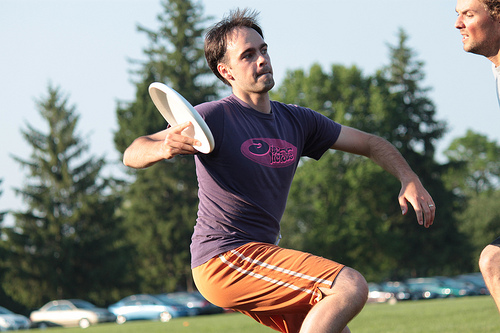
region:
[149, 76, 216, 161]
the frisbee is white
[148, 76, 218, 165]
man holding the frisbee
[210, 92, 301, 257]
the shirt is purple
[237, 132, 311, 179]
the logo is pink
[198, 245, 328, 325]
the shorts are orange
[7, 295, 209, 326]
the cars are parked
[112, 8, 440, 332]
jumping man holding frisbee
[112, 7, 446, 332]
white adult brown haired male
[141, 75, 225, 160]
white plastic flying disc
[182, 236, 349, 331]
men's orange and white shorts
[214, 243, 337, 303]
white stripes on short's leg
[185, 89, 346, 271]
men's purple tee shirt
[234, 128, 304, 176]
pink logo on tee shirt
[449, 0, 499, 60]
blonde white male head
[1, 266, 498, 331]
row of cars parked near trees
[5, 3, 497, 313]
row of pine trees near cars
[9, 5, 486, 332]
a man playing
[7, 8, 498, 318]
a scene during the day time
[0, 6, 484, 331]
a scene outside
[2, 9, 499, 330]
a scene at a park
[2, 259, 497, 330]
a row of cars in the background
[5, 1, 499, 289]
some trees in the distance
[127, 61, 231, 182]
a white disc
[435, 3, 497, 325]
someone on the right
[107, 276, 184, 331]
a blue car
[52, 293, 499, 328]
a green field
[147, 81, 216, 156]
a white frisbee in a hand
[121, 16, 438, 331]
a man in a purple shirt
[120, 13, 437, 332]
a man in orange shorts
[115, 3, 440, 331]
a man with floppy hair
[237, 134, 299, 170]
a purple logo on a shirt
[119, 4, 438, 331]
a man playing frisbee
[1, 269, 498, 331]
a row of parked cars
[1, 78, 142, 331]
a tall pine tree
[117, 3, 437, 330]
a man about to throw a frisbee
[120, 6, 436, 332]
a man playing in a park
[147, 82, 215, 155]
A white frisbee.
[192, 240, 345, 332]
Orange shorts with white stripes.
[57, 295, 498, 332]
A green grassy field.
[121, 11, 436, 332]
Brown haired man in orange shorts.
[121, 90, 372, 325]
a man with purple t shirt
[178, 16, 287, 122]
a man with brown hair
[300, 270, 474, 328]
a line of cars in the parking lot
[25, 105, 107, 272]
a big green pin tree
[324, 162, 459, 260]
a man with a ring on his finger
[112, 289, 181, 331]
a lite blue car in the parking lot